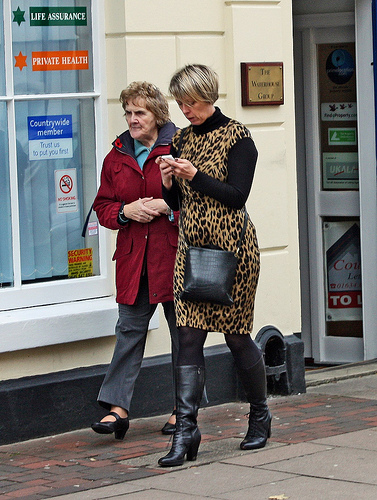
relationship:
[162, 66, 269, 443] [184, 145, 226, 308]
woman in dress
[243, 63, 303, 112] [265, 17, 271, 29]
plaque on wall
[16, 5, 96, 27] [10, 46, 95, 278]
sticker in window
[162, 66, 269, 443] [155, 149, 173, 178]
woman holding cell phone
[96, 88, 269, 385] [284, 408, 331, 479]
women on sidewalk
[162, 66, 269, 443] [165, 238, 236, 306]
woman with black purse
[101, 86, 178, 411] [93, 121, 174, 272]
lady in red coat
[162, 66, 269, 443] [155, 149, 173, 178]
woman on cell phone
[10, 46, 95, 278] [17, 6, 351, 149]
window in building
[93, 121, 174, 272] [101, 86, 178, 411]
coat on lady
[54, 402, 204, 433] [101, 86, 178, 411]
shoes on lady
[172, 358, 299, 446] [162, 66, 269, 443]
boots on woman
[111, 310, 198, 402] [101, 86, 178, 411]
gray pants on lady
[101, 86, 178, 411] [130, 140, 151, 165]
lady in blue shirt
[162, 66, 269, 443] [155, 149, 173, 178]
woman using cell phone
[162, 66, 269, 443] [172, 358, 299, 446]
woman in boots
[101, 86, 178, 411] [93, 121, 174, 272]
lady wears coat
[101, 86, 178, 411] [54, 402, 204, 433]
lady wears shoes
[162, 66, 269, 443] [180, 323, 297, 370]
woman wears black stockings